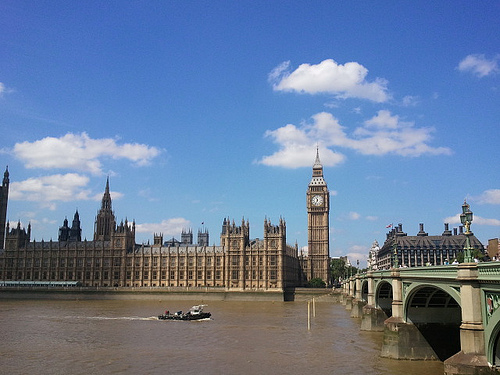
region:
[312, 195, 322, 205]
clock on side of tower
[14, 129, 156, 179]
white clouds in sky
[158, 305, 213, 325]
boat riding down river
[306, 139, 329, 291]
large tower with clock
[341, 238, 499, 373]
green bridge over water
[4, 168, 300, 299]
brown elaborately decorated building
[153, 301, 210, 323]
black and white boat approaching bridge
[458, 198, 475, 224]
street lights near bridge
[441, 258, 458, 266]
people crossing green bridge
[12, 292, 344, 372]
large river with brown water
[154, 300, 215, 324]
Boat in the water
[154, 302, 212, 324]
Boat is in the water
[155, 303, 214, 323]
Boat in the brown water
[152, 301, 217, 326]
Boat is in the brown water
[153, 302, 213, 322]
Black boat in the water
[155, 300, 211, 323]
Black boat is in the water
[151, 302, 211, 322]
Black boat in the brown water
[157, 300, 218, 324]
Black boat is in the brown water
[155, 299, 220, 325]
Boat in the river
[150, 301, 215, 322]
Boat is in the river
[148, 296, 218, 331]
the boat on the water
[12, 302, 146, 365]
the water is calm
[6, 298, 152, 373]
the water is muddy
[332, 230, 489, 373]
the bridge over the water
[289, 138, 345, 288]
the tower beside the building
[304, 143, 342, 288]
the tower is Big Ben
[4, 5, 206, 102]
the clear blue sky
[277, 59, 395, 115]
the clouds in the sky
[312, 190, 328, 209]
the clock on the tower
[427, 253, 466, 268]
people on the bridge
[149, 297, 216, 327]
A boat is in the water.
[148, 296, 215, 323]
A ship is in the water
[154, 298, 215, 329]
The colors of a boat are black, white, and red.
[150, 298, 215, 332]
The colors of a ship are black, white, and red.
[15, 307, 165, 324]
A boat is creating waves in the water.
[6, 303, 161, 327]
A ship is creating waves in the water.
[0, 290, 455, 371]
The color of a body of water is brown.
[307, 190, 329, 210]
A big clock is in the background.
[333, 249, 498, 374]
The sun is shining on a bridge.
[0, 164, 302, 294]
The colors of a building are brown and black.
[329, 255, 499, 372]
Green bridge on river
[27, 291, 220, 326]
tour boat with long wake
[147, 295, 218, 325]
Black tour boat on water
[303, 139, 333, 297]
tall brownstone clock tower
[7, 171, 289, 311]
building with windows along river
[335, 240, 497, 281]
people walking on green bridge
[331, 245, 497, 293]
walkway along green river bridge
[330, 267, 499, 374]
cement pylons on green bridge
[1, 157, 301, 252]
pointed towers on buildings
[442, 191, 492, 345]
Street lamp on green river bridge